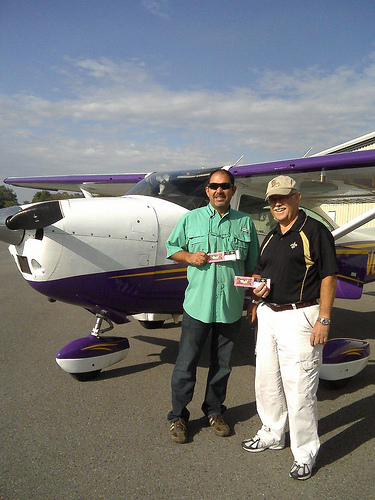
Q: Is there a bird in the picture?
A: No, there are no birds.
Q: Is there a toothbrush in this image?
A: No, there are no toothbrushes.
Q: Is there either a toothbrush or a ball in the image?
A: No, there are no toothbrushes or balls.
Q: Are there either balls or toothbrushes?
A: No, there are no toothbrushes or balls.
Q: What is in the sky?
A: The clouds are in the sky.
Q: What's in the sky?
A: The clouds are in the sky.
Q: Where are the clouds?
A: The clouds are in the sky.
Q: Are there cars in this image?
A: No, there are no cars.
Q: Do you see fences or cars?
A: No, there are no cars or fences.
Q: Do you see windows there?
A: Yes, there is a window.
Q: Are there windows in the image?
A: Yes, there is a window.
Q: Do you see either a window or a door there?
A: Yes, there is a window.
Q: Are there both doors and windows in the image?
A: No, there is a window but no doors.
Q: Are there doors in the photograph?
A: No, there are no doors.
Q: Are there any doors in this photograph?
A: No, there are no doors.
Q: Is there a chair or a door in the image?
A: No, there are no doors or chairs.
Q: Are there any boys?
A: No, there are no boys.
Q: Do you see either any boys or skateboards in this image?
A: No, there are no boys or skateboards.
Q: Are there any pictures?
A: No, there are no pictures.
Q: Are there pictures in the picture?
A: No, there are no pictures.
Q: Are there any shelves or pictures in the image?
A: No, there are no pictures or shelves.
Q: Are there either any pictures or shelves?
A: No, there are no pictures or shelves.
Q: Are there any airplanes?
A: Yes, there is an airplane.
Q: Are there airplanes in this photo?
A: Yes, there is an airplane.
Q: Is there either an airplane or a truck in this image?
A: Yes, there is an airplane.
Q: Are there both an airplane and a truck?
A: No, there is an airplane but no trucks.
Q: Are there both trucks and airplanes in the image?
A: No, there is an airplane but no trucks.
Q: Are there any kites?
A: No, there are no kites.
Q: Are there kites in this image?
A: No, there are no kites.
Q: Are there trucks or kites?
A: No, there are no kites or trucks.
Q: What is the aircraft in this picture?
A: The aircraft is an airplane.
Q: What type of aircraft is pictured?
A: The aircraft is an airplane.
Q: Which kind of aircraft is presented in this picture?
A: The aircraft is an airplane.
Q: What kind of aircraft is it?
A: The aircraft is an airplane.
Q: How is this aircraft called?
A: That is an airplane.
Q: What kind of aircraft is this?
A: That is an airplane.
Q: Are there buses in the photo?
A: No, there are no buses.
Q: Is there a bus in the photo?
A: No, there are no buses.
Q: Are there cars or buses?
A: No, there are no buses or cars.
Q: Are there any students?
A: No, there are no students.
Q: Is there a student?
A: No, there are no students.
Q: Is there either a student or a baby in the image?
A: No, there are no students or babies.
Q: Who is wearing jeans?
A: The man is wearing jeans.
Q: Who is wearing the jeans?
A: The man is wearing jeans.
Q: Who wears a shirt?
A: The man wears a shirt.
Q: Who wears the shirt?
A: The man wears a shirt.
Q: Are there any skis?
A: No, there are no skis.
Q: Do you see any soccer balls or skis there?
A: No, there are no skis or soccer balls.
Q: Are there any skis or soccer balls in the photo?
A: No, there are no skis or soccer balls.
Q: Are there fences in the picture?
A: No, there are no fences.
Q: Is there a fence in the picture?
A: No, there are no fences.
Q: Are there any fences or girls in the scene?
A: No, there are no fences or girls.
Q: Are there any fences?
A: No, there are no fences.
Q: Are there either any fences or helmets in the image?
A: No, there are no fences or helmets.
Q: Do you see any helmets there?
A: No, there are no helmets.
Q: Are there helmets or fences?
A: No, there are no helmets or fences.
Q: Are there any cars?
A: No, there are no cars.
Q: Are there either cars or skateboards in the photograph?
A: No, there are no cars or skateboards.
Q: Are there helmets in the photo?
A: No, there are no helmets.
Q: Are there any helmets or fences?
A: No, there are no helmets or fences.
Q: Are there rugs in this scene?
A: No, there are no rugs.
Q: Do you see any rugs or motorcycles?
A: No, there are no rugs or motorcycles.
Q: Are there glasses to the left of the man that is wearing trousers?
A: Yes, there are glasses to the left of the man.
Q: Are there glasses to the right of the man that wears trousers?
A: No, the glasses are to the left of the man.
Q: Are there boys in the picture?
A: No, there are no boys.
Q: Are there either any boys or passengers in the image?
A: No, there are no boys or passengers.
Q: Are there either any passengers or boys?
A: No, there are no boys or passengers.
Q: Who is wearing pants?
A: The man is wearing pants.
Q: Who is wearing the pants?
A: The man is wearing pants.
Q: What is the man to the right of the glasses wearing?
A: The man is wearing trousers.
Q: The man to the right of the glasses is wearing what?
A: The man is wearing trousers.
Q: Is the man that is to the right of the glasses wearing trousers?
A: Yes, the man is wearing trousers.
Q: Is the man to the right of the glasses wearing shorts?
A: No, the man is wearing trousers.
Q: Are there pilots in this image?
A: No, there are no pilots.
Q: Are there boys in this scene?
A: No, there are no boys.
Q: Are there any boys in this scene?
A: No, there are no boys.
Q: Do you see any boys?
A: No, there are no boys.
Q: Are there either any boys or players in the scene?
A: No, there are no boys or players.